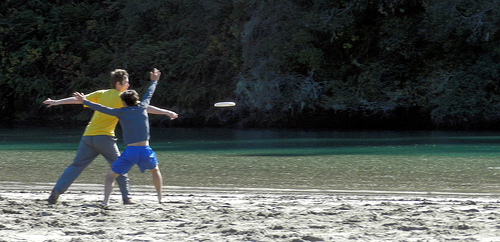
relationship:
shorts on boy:
[111, 149, 158, 176] [70, 80, 179, 211]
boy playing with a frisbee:
[45, 69, 179, 206] [214, 100, 235, 107]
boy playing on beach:
[70, 67, 180, 210] [66, 210, 496, 236]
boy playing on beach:
[45, 69, 179, 206] [66, 210, 496, 236]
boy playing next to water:
[70, 67, 180, 210] [25, 112, 499, 196]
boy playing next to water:
[45, 69, 179, 206] [25, 112, 499, 196]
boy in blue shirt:
[70, 67, 180, 210] [84, 80, 156, 141]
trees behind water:
[3, 0, 498, 126] [1, 126, 498, 183]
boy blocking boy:
[70, 67, 180, 210] [45, 69, 179, 206]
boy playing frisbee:
[45, 69, 179, 206] [211, 99, 238, 109]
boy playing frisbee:
[70, 67, 180, 210] [211, 99, 238, 109]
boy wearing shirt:
[70, 67, 180, 210] [113, 102, 156, 143]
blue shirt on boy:
[84, 80, 156, 145] [40, 75, 210, 205]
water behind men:
[0, 135, 496, 192] [38, 63, 178, 213]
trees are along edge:
[0, 0, 499, 126] [2, 125, 487, 148]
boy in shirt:
[45, 69, 179, 206] [82, 89, 128, 137]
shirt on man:
[82, 90, 124, 137] [31, 69, 178, 199]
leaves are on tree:
[416, 73, 481, 116] [427, 64, 498, 129]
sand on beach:
[134, 192, 453, 241] [8, 193, 495, 237]